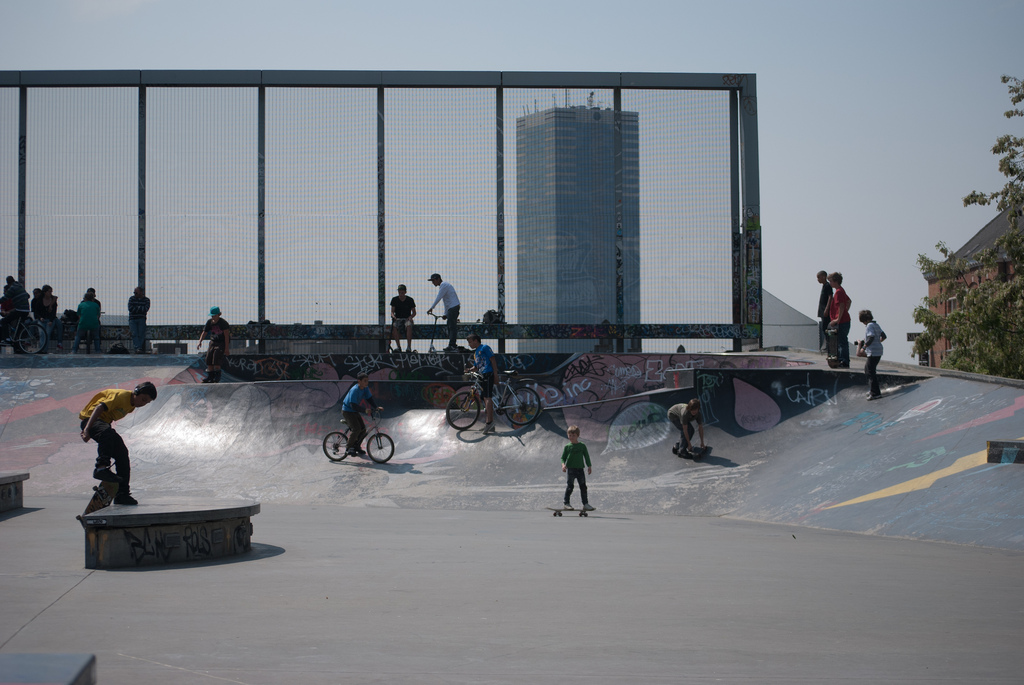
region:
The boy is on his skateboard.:
[65, 369, 164, 516]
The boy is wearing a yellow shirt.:
[78, 367, 168, 510]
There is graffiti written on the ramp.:
[68, 492, 261, 569]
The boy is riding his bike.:
[316, 369, 403, 465]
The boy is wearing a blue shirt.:
[313, 363, 396, 463]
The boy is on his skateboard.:
[540, 416, 599, 525]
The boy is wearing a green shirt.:
[541, 423, 605, 522]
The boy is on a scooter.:
[405, 259, 464, 362]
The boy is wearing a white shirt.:
[427, 265, 463, 345]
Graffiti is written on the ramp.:
[797, 383, 1022, 567]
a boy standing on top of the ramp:
[78, 375, 165, 506]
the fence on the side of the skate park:
[0, 72, 757, 345]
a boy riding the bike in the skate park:
[319, 370, 393, 468]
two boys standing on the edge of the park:
[809, 269, 854, 365]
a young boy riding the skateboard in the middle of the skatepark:
[550, 421, 598, 523]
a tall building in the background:
[517, 104, 648, 360]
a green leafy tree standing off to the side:
[916, 73, 1022, 397]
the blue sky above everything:
[8, 7, 1020, 346]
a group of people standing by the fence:
[2, 277, 157, 355]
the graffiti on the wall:
[752, 372, 847, 426]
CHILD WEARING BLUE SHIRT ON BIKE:
[315, 373, 405, 469]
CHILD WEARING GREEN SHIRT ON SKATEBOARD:
[545, 421, 604, 513]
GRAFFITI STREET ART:
[0, 353, 1022, 566]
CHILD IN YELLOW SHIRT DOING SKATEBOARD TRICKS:
[58, 374, 157, 514]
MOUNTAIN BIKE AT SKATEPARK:
[432, 356, 554, 436]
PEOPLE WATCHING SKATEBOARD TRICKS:
[808, 258, 895, 402]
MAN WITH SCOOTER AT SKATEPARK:
[420, 268, 477, 363]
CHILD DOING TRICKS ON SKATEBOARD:
[656, 394, 724, 465]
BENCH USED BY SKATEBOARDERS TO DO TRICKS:
[71, 483, 264, 573]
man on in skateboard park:
[842, 292, 915, 411]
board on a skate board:
[64, 352, 163, 521]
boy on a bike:
[305, 367, 404, 466]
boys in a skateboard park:
[797, 248, 862, 384]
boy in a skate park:
[409, 258, 467, 354]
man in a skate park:
[108, 276, 165, 350]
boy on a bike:
[447, 319, 531, 441]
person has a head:
[355, 372, 366, 393]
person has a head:
[467, 331, 481, 352]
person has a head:
[561, 428, 578, 448]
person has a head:
[688, 390, 699, 411]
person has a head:
[827, 274, 840, 291]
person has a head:
[858, 311, 872, 328]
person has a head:
[814, 271, 831, 292]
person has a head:
[399, 283, 406, 296]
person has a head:
[210, 306, 218, 323]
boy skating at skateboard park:
[42, 371, 170, 509]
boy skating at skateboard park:
[542, 412, 613, 545]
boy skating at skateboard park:
[178, 294, 243, 392]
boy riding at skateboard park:
[299, 368, 416, 476]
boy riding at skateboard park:
[441, 325, 536, 444]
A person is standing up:
[555, 425, 604, 511]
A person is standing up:
[70, 381, 168, 525]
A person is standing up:
[461, 337, 513, 407]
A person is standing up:
[422, 267, 474, 353]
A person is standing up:
[384, 277, 414, 353]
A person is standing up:
[824, 272, 853, 348]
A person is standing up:
[856, 310, 896, 387]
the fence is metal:
[115, 10, 627, 324]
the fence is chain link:
[128, 74, 629, 312]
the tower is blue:
[473, 63, 701, 403]